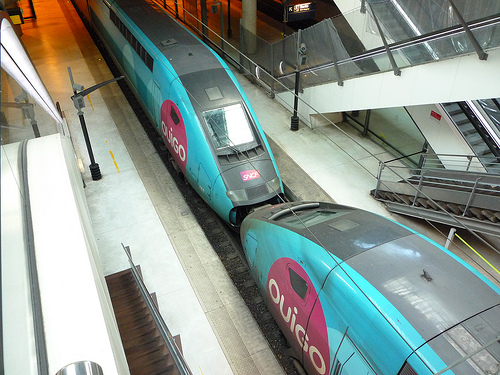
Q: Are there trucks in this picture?
A: No, there are no trucks.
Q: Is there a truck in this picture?
A: No, there are no trucks.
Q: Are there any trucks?
A: No, there are no trucks.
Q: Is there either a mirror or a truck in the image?
A: No, there are no trucks or mirrors.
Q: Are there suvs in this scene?
A: No, there are no suvs.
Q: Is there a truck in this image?
A: No, there are no trucks.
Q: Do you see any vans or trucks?
A: No, there are no trucks or vans.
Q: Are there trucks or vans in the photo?
A: No, there are no trucks or vans.